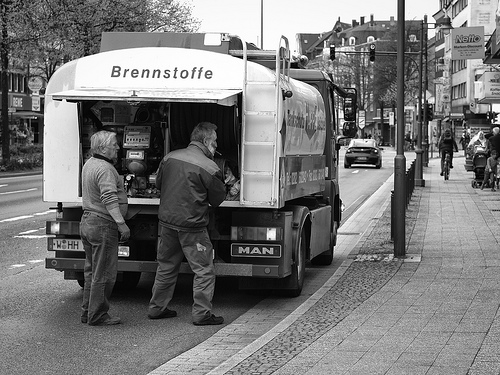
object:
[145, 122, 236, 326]
man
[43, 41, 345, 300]
truck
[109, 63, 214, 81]
logo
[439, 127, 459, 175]
person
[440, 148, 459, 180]
bike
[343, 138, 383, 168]
car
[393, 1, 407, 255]
pole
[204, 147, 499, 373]
sidewalk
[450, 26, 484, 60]
sign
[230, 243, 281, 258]
sign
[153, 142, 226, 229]
jacket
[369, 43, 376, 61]
traffic ligh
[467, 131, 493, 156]
woman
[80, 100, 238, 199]
goods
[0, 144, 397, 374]
road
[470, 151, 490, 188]
stroller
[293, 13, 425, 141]
buildings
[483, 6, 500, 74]
building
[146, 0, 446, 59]
sky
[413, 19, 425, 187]
pole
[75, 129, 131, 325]
old man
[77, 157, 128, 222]
shirt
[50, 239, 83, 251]
plate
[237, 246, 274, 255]
word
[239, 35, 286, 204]
ladder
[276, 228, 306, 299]
back wheel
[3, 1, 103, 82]
tree